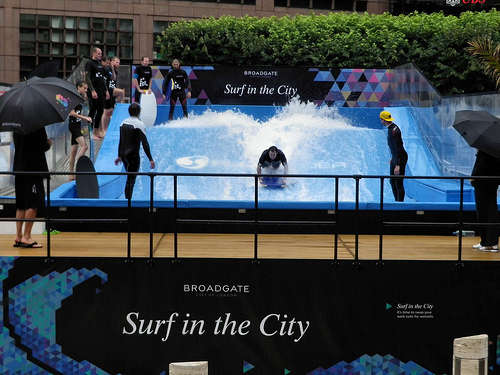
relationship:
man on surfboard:
[253, 144, 290, 178] [254, 170, 286, 190]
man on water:
[253, 144, 290, 178] [118, 97, 401, 197]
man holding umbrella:
[10, 117, 50, 244] [1, 69, 83, 128]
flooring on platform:
[4, 229, 493, 261] [2, 169, 498, 370]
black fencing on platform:
[4, 168, 499, 263] [3, 228, 498, 373]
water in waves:
[118, 101, 453, 211] [232, 109, 313, 146]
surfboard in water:
[262, 177, 284, 187] [152, 125, 392, 200]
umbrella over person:
[1, 73, 83, 131] [11, 122, 52, 248]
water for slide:
[146, 95, 382, 202] [126, 119, 438, 201]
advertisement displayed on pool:
[120, 311, 310, 343] [136, 112, 388, 180]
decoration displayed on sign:
[271, 347, 440, 373] [2, 258, 489, 373]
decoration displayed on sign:
[3, 257, 112, 373] [2, 258, 489, 373]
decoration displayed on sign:
[314, 67, 434, 106] [2, 258, 489, 373]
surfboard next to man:
[138, 85, 162, 131] [127, 50, 162, 122]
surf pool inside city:
[44, 66, 499, 235] [0, 0, 498, 374]